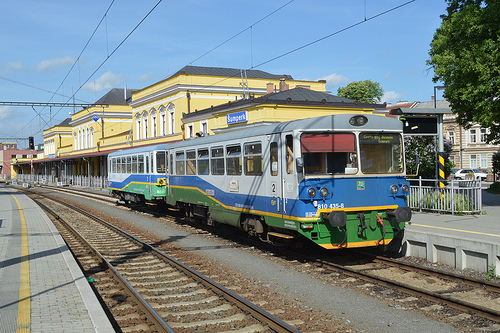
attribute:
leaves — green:
[455, 70, 468, 80]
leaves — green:
[441, 30, 470, 53]